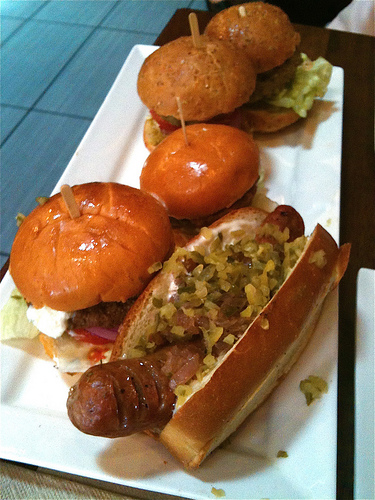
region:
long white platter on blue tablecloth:
[3, 3, 343, 495]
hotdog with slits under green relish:
[67, 203, 329, 436]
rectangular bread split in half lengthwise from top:
[105, 200, 341, 463]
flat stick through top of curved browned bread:
[9, 176, 168, 296]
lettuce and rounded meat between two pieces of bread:
[210, 2, 330, 132]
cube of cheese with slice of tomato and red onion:
[22, 300, 112, 345]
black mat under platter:
[157, 0, 367, 264]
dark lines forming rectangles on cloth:
[0, 0, 201, 204]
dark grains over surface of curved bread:
[144, 36, 243, 99]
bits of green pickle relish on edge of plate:
[268, 372, 332, 496]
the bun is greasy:
[30, 180, 120, 302]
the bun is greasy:
[151, 137, 259, 227]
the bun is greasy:
[129, 123, 237, 206]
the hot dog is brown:
[69, 249, 216, 452]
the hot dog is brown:
[193, 178, 315, 272]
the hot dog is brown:
[81, 339, 228, 434]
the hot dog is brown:
[121, 261, 247, 392]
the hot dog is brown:
[212, 204, 344, 304]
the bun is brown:
[67, 224, 107, 263]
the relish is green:
[214, 254, 249, 288]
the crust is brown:
[238, 351, 254, 379]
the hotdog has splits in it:
[102, 364, 157, 422]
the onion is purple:
[94, 325, 113, 344]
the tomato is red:
[76, 330, 94, 342]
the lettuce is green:
[299, 71, 321, 102]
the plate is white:
[283, 406, 319, 445]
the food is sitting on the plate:
[150, 46, 336, 317]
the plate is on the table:
[318, 40, 356, 105]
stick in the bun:
[40, 170, 106, 242]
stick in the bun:
[167, 90, 205, 154]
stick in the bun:
[177, 13, 217, 73]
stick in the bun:
[231, 1, 249, 22]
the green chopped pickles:
[184, 250, 241, 319]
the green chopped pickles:
[145, 246, 241, 355]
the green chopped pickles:
[235, 240, 286, 311]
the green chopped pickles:
[201, 268, 285, 315]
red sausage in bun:
[62, 201, 307, 440]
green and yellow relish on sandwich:
[125, 211, 329, 404]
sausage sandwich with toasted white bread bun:
[60, 201, 355, 473]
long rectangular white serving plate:
[0, 42, 349, 498]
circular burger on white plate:
[136, 120, 267, 249]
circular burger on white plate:
[133, 27, 259, 164]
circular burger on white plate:
[194, 0, 334, 136]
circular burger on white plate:
[4, 175, 199, 375]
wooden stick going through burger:
[57, 181, 117, 380]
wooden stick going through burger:
[186, 7, 207, 145]